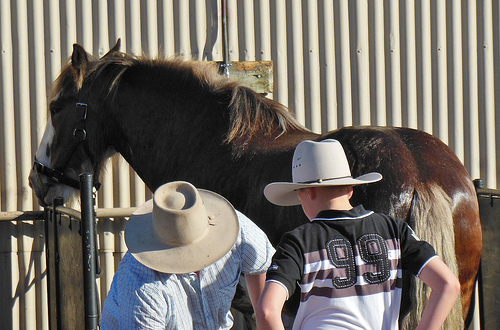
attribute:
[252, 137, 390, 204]
hat — leather, white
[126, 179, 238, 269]
hat — white, man's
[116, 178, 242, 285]
hat — white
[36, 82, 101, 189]
bridle — brown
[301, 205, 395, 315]
shirt — white, black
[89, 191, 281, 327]
shirt — short sleeve, stripe, blue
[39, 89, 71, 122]
eye — black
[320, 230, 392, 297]
number — ninety-nine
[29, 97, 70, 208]
face — white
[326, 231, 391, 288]
number — 99, black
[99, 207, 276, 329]
shirt — plaid, blue, button up, pale blue, white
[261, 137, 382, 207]
hat — white, cowboy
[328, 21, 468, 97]
metal wall — white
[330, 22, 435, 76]
wall — beige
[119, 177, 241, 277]
cowboy hat — white, leather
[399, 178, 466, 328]
tail — tan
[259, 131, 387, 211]
hat — white, cowboy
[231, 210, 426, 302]
shirt — striped, brown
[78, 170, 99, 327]
post — metal, black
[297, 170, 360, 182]
rope — black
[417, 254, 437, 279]
stripe — white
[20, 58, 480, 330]
horse — brown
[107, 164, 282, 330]
man — standing